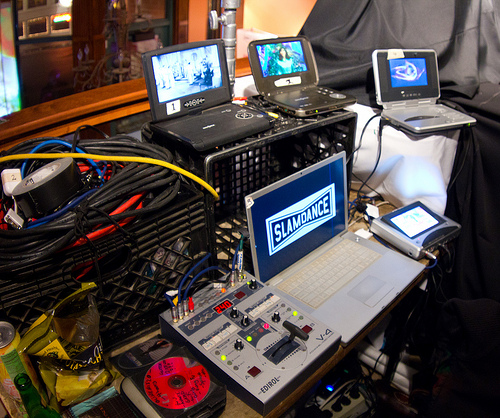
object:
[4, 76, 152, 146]
ledge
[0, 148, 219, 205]
cable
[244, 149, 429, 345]
laptop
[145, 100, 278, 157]
black crate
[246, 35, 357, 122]
dvd players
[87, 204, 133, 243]
cable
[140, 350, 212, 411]
disc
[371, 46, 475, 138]
laptop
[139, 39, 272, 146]
laptop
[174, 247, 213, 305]
cable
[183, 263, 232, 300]
cable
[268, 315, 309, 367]
switch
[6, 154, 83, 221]
tape